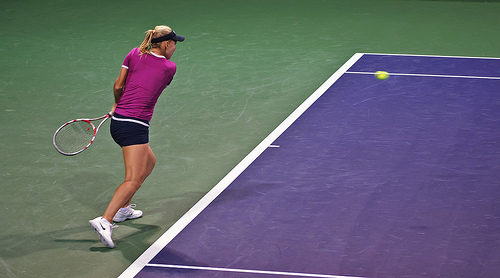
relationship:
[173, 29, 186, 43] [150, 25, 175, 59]
visor on head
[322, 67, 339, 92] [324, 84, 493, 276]
baseline of court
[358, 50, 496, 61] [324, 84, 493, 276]
sideline on court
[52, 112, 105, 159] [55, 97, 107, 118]
racket in motion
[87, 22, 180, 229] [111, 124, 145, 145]
woman has shorts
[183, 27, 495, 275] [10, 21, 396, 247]
area for playing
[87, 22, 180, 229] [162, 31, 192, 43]
woman has cap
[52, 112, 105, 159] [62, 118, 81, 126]
racket with colors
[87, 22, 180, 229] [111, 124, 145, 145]
lady wearing shorts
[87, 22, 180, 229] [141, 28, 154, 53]
lady has a pony tail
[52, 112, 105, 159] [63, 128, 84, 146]
racquet has netting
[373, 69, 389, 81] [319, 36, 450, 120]
ball in air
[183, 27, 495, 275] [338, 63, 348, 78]
court has a line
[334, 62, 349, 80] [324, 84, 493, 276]
edge on court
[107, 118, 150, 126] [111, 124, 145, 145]
edge on short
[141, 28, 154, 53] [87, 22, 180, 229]
pony tail on woman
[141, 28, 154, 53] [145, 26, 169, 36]
pony tail in hair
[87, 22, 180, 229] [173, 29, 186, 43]
woman wearing visor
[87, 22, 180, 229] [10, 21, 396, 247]
woman playing tennis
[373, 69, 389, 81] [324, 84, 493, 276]
ball on court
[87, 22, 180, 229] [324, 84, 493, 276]
lady on court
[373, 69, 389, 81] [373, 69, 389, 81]
ball in ball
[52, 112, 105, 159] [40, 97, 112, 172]
racquet in view